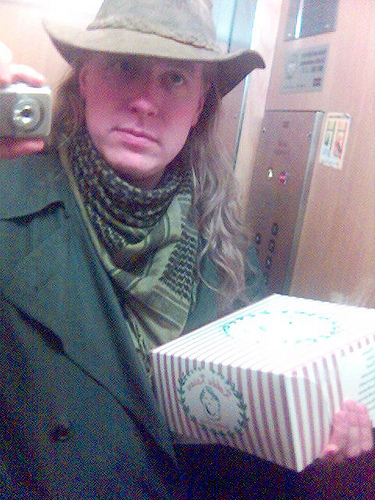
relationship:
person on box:
[197, 390, 232, 424] [144, 292, 375, 475]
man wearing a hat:
[2, 1, 370, 498] [42, 1, 263, 94]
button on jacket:
[50, 419, 78, 444] [1, 147, 310, 499]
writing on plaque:
[298, 48, 329, 74] [274, 48, 332, 92]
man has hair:
[2, 1, 370, 498] [41, 69, 253, 303]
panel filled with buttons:
[243, 105, 327, 301] [249, 213, 284, 291]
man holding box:
[2, 1, 370, 498] [144, 292, 375, 475]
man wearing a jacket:
[2, 1, 370, 498] [1, 147, 310, 499]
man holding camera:
[2, 1, 370, 498] [1, 87, 53, 138]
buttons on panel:
[249, 213, 284, 291] [243, 105, 327, 301]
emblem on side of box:
[174, 366, 254, 439] [144, 292, 375, 475]